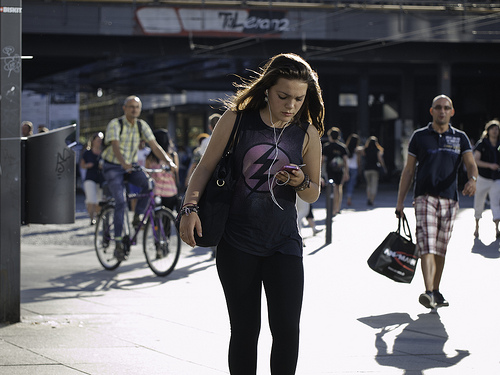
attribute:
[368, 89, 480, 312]
man — walking, balding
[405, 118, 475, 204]
shirt — blue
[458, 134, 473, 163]
sleeve — short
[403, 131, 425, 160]
sleeve — short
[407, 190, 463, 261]
shorts — checkered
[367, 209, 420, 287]
bag — black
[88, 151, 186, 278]
bike — purple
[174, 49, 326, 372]
girl — walking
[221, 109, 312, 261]
shirt — sleeveless, blue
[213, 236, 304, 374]
leggings — black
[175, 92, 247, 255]
purse — black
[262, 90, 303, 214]
earphones — white